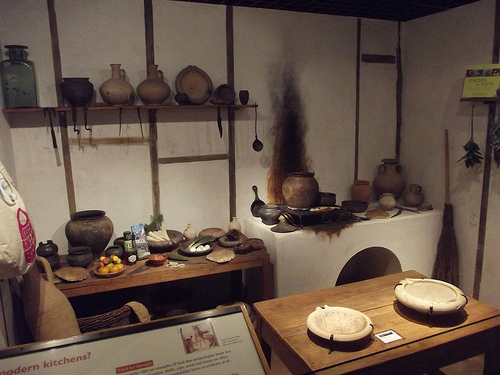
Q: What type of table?
A: Wood.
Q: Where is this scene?
A: In a museum.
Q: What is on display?
A: Artifacts.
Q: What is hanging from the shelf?
A: Utensils.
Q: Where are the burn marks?
A: Around the stove.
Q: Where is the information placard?
A: In front of the kitchen mock-up.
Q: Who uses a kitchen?
A: Cooks.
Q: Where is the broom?
A: In the right corner by the stove.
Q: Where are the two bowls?
A: On the wooden table.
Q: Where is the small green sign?
A: On the right side by the broom.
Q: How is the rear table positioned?
A: By the back wall.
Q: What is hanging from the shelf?
A: Utensils.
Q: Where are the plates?
A: On the table.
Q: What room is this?
A: Kitchen.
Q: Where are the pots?
A: On the shelf.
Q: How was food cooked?
A: Over a fireplace.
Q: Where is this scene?
A: A kitchen.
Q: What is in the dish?
A: Vegetables.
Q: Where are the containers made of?
A: Clay.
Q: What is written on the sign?
A: Modern kitchen.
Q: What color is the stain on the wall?
A: Brown.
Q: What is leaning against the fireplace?
A: A broom.